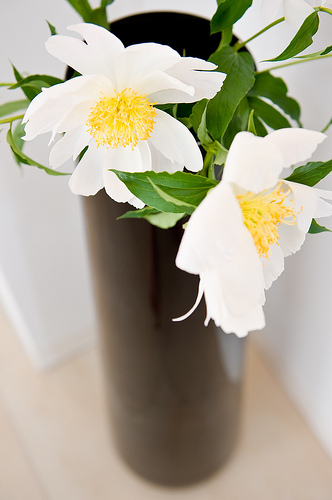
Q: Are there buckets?
A: No, there are no buckets.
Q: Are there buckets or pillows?
A: No, there are no buckets or pillows.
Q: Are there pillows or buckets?
A: No, there are no buckets or pillows.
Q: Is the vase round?
A: Yes, the vase is round.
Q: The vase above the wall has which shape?
A: The vase is round.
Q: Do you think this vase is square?
A: No, the vase is round.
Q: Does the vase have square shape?
A: No, the vase is round.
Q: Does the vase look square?
A: No, the vase is round.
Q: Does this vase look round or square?
A: The vase is round.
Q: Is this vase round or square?
A: The vase is round.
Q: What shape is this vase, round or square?
A: The vase is round.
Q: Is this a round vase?
A: Yes, this is a round vase.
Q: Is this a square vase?
A: No, this is a round vase.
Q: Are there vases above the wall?
A: Yes, there is a vase above the wall.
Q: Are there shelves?
A: No, there are no shelves.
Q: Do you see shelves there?
A: No, there are no shelves.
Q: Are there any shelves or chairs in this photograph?
A: No, there are no shelves or chairs.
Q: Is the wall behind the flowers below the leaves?
A: Yes, the wall is behind the flowers.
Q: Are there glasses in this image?
A: No, there are no glasses.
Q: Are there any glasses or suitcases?
A: No, there are no glasses or suitcases.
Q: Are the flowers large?
A: Yes, the flowers are large.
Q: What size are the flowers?
A: The flowers are large.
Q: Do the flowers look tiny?
A: No, the flowers are large.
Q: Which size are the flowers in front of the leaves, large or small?
A: The flowers are large.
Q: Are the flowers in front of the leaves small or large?
A: The flowers are large.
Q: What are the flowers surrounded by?
A: The flowers are surrounded by the leaves.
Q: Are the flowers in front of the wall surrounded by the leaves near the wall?
A: Yes, the flowers are surrounded by the leaves.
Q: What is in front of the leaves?
A: The flowers are in front of the leaves.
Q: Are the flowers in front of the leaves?
A: Yes, the flowers are in front of the leaves.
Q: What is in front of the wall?
A: The flowers are in front of the wall.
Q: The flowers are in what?
A: The flowers are in the vase.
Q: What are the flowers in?
A: The flowers are in the vase.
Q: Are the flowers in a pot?
A: No, the flowers are in a vase.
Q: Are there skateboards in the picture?
A: No, there are no skateboards.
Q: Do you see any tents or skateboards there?
A: No, there are no skateboards or tents.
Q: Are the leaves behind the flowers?
A: Yes, the leaves are behind the flowers.